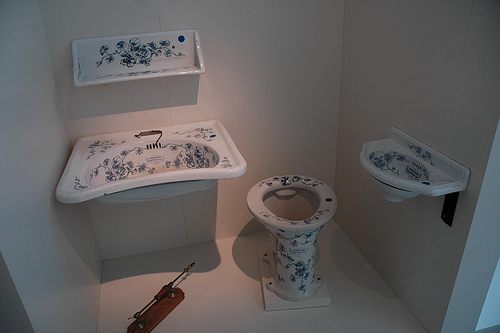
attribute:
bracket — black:
[433, 184, 465, 235]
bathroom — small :
[47, 33, 467, 290]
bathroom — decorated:
[1, 2, 499, 332]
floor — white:
[93, 212, 428, 330]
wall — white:
[40, 0, 345, 262]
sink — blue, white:
[357, 126, 470, 201]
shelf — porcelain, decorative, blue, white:
[57, 20, 210, 103]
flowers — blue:
[90, 35, 191, 75]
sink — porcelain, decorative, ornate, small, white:
[355, 113, 477, 220]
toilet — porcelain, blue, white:
[237, 165, 350, 316]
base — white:
[254, 238, 338, 314]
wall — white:
[327, 0, 499, 333]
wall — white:
[1, 3, 105, 332]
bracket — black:
[435, 186, 468, 228]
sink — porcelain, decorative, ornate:
[43, 106, 249, 220]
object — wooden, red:
[105, 257, 206, 333]